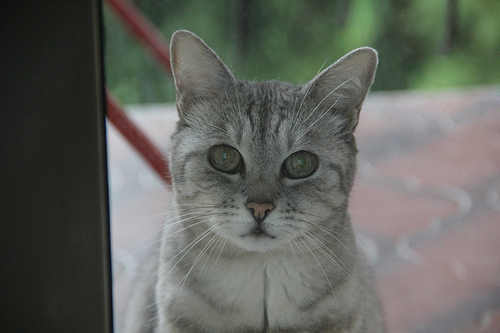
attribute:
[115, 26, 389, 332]
cat — gray, white, beautiful, looking, grey, small, cute, innocent, striped gray, sitting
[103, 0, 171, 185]
rails — red, angled, poles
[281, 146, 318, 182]
left eye — yellow, little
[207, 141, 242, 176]
right eye — yellow, little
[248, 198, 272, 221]
nose — little, pink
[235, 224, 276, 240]
mouth — black, little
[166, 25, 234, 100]
right ear — furry, gray, upright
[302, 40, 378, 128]
left ear — furry, gray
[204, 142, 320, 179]
eyes — wide open, round, green, reflective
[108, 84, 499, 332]
floor — bricked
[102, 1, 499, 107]
trees — back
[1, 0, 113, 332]
wall — brown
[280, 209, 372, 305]
whiskers — white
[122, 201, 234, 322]
whiskers — white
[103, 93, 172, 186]
rail — red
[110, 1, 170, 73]
rail — red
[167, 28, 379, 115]
ears — pointy